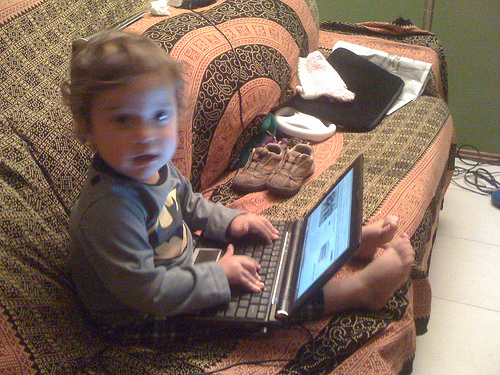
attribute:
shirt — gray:
[64, 164, 242, 329]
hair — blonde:
[38, 20, 203, 182]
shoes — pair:
[231, 132, 309, 196]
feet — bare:
[346, 211, 416, 312]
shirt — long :
[84, 201, 233, 319]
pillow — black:
[285, 31, 415, 135]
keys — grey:
[219, 247, 277, 291]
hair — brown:
[62, 30, 187, 137]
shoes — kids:
[232, 130, 341, 202]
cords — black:
[455, 147, 498, 193]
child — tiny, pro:
[62, 29, 419, 352]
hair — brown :
[57, 28, 188, 143]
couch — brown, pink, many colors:
[6, 2, 461, 367]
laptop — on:
[209, 174, 424, 335]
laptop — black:
[177, 153, 363, 328]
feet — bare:
[353, 227, 415, 312]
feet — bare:
[353, 212, 401, 264]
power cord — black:
[445, 140, 497, 197]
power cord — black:
[185, 3, 247, 144]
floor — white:
[427, 194, 493, 369]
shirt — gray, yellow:
[52, 146, 272, 321]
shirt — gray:
[59, 159, 246, 319]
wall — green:
[317, 1, 499, 161]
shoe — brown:
[265, 141, 312, 195]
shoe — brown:
[231, 142, 286, 192]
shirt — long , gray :
[69, 152, 234, 314]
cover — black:
[286, 47, 402, 132]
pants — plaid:
[109, 309, 229, 342]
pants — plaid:
[97, 314, 247, 348]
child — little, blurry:
[42, 25, 464, 338]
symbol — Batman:
[141, 179, 191, 269]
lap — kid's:
[150, 317, 290, 335]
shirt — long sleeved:
[91, 193, 233, 305]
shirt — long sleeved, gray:
[74, 187, 256, 304]